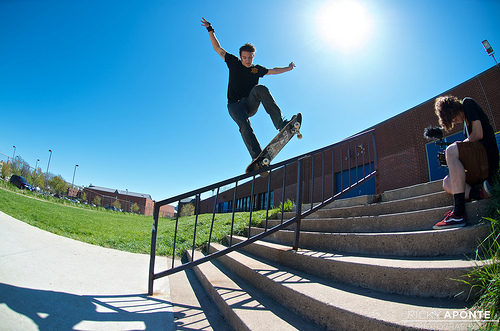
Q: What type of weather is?
A: It is clear.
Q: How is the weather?
A: It is clear.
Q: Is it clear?
A: Yes, it is clear.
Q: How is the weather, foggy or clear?
A: It is clear.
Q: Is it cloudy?
A: No, it is clear.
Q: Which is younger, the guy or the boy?
A: The boy is younger than the guy.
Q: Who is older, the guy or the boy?
A: The guy is older than the boy.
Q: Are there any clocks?
A: No, there are no clocks.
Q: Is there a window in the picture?
A: Yes, there is a window.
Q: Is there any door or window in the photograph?
A: Yes, there is a window.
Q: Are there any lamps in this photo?
A: Yes, there is a lamp.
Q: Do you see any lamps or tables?
A: Yes, there is a lamp.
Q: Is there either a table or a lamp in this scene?
A: Yes, there is a lamp.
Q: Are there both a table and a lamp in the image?
A: No, there is a lamp but no tables.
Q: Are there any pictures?
A: No, there are no pictures.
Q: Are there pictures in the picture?
A: No, there are no pictures.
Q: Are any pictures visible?
A: No, there are no pictures.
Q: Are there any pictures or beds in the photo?
A: No, there are no pictures or beds.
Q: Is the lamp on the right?
A: Yes, the lamp is on the right of the image.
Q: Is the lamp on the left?
A: No, the lamp is on the right of the image.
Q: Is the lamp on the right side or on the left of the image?
A: The lamp is on the right of the image.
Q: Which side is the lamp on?
A: The lamp is on the right of the image.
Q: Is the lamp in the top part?
A: Yes, the lamp is in the top of the image.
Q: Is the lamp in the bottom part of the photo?
A: No, the lamp is in the top of the image.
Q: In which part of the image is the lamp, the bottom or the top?
A: The lamp is in the top of the image.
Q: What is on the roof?
A: The lamp is on the roof.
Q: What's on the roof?
A: The lamp is on the roof.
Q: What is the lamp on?
A: The lamp is on the roof.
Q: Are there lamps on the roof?
A: Yes, there is a lamp on the roof.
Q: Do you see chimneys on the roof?
A: No, there is a lamp on the roof.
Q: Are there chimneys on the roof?
A: No, there is a lamp on the roof.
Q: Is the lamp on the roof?
A: Yes, the lamp is on the roof.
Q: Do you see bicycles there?
A: No, there are no bicycles.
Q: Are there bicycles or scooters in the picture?
A: No, there are no bicycles or scooters.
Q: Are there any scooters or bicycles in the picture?
A: No, there are no bicycles or scooters.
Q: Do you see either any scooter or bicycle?
A: No, there are no bicycles or scooters.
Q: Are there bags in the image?
A: No, there are no bags.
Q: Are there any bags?
A: No, there are no bags.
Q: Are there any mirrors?
A: No, there are no mirrors.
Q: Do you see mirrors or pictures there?
A: No, there are no mirrors or pictures.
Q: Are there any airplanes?
A: No, there are no airplanes.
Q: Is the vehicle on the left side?
A: Yes, the vehicle is on the left of the image.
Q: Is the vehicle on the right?
A: No, the vehicle is on the left of the image.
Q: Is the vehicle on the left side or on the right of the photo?
A: The vehicle is on the left of the image.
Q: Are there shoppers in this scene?
A: No, there are no shoppers.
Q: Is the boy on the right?
A: Yes, the boy is on the right of the image.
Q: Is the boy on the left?
A: No, the boy is on the right of the image.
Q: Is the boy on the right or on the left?
A: The boy is on the right of the image.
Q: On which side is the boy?
A: The boy is on the right of the image.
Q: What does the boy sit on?
A: The boy sits on the staircase.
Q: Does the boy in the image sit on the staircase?
A: Yes, the boy sits on the staircase.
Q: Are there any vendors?
A: No, there are no vendors.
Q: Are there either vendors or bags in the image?
A: No, there are no vendors or bags.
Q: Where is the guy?
A: The guy is on the sidewalk.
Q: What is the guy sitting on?
A: The guy is sitting on the staircase.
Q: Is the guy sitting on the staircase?
A: Yes, the guy is sitting on the staircase.